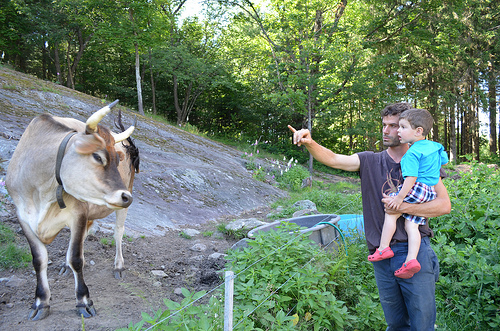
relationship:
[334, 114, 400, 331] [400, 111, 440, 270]
man holding kid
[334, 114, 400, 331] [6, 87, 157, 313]
man watching cow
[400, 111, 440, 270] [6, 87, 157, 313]
kid watching cow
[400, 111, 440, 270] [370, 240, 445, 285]
kid wears shoes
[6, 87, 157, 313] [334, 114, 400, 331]
cow watching man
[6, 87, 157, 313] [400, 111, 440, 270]
cow watching kid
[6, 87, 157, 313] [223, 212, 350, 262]
cow drinking bucket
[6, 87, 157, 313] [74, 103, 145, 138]
cow has horns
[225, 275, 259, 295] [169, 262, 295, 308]
part of fence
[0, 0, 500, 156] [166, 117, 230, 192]
leaves on hill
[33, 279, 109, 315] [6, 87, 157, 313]
hooves on cow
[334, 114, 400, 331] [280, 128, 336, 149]
man uses hand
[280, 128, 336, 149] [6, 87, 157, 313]
hand points at cow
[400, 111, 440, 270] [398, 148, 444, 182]
kid wearing shirt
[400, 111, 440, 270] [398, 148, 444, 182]
kid in shirt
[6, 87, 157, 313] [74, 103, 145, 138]
cow with horns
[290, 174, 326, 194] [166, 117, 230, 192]
grass on hill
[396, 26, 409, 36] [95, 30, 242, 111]
leaves on trees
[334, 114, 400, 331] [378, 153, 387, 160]
man wears shirt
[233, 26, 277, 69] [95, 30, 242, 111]
sun on trees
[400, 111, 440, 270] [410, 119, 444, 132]
kid has hair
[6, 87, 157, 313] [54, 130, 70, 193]
cow wears collar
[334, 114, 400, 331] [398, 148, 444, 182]
man wears shirt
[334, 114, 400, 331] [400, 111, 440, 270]
man with kid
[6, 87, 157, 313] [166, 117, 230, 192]
cow on hill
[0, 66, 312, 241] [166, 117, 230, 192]
hill on hill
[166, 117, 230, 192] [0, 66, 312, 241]
hill has hill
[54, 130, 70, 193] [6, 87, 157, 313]
collar on cow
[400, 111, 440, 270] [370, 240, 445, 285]
kid wearing shoes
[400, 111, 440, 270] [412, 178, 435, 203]
kid wearing shorts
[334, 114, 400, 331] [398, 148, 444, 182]
man in shirt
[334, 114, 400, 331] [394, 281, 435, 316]
man in jeans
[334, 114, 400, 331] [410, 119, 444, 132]
man has hair